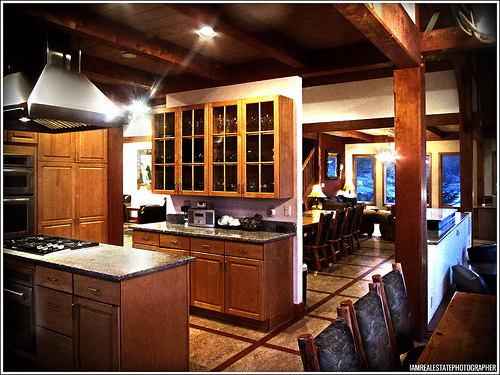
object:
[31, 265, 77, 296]
drawer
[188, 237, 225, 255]
drawer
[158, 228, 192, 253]
drawer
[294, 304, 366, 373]
chair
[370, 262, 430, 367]
chair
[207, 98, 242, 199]
glass door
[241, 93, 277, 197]
door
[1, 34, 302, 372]
kitchen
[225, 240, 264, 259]
drawer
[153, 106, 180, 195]
glass cabinet-doors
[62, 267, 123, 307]
drawer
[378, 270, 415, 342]
back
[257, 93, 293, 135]
cabinet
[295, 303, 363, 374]
back